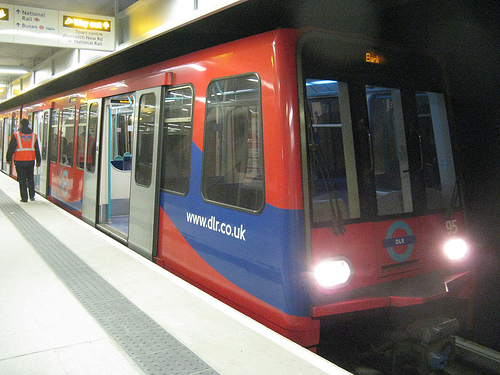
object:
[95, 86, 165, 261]
door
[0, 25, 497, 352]
subway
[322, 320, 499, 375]
rail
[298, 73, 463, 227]
front window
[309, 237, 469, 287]
light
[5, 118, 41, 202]
man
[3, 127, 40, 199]
uniform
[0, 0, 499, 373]
station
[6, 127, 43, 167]
sweater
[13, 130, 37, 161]
vest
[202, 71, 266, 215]
window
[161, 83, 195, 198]
window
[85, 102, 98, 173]
window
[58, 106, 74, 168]
window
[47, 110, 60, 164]
window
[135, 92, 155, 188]
window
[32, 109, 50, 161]
window